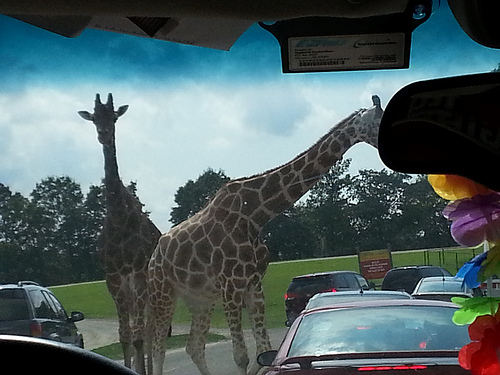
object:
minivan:
[0, 280, 85, 349]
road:
[79, 312, 108, 349]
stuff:
[426, 170, 498, 375]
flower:
[426, 174, 500, 201]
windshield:
[285, 305, 475, 357]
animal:
[146, 94, 386, 375]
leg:
[184, 290, 219, 375]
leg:
[219, 273, 250, 375]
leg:
[241, 282, 274, 374]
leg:
[144, 276, 176, 375]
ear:
[114, 104, 130, 117]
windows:
[26, 289, 69, 321]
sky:
[151, 84, 280, 160]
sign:
[357, 247, 394, 280]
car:
[381, 264, 455, 295]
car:
[284, 271, 377, 322]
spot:
[170, 240, 195, 270]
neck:
[237, 112, 356, 236]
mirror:
[377, 71, 499, 193]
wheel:
[45, 333, 63, 343]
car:
[0, 280, 84, 350]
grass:
[287, 263, 321, 272]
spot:
[275, 173, 299, 201]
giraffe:
[76, 93, 162, 375]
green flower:
[449, 295, 499, 327]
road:
[206, 338, 232, 375]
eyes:
[92, 117, 97, 123]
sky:
[2, 44, 78, 169]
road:
[162, 350, 196, 375]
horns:
[94, 92, 115, 108]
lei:
[426, 173, 499, 375]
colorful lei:
[426, 171, 500, 375]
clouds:
[2, 27, 91, 180]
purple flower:
[441, 194, 500, 249]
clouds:
[300, 96, 327, 128]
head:
[78, 92, 130, 144]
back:
[255, 299, 479, 375]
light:
[290, 340, 363, 355]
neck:
[97, 137, 143, 226]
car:
[252, 298, 476, 375]